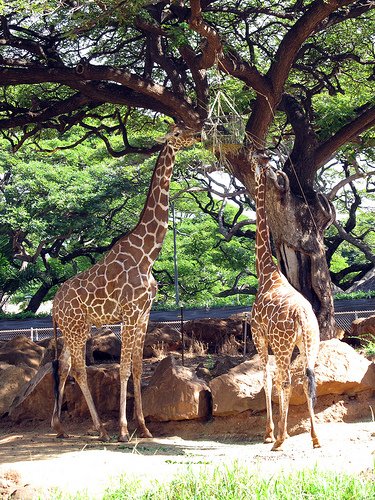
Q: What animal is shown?
A: Giraffe.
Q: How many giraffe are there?
A: Two.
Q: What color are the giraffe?
A: Brown and white.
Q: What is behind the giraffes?
A: Rocks.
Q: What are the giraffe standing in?
A: Dirt.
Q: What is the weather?
A: Sunny.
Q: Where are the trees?
A: Background.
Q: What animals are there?
A: Giraffe.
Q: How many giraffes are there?
A: 2.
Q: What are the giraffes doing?
A: Feeding.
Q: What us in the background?
A: Trees.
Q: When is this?
A: Afternoon.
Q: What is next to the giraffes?
A: Rocks.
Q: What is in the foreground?
A: Grass.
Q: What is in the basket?
A: Food.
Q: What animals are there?
A: Giraffes.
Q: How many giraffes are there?
A: 2.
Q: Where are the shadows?
A: Everywhere.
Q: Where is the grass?
A: Forefront.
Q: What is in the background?
A: Trees.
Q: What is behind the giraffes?
A: Rocks.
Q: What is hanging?
A: Basket.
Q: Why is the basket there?
A: Food.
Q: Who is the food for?
A: Giraffes.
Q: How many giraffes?
A: 2.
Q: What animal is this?
A: Giraffe.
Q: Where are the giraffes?
A: Enclosure in zoo.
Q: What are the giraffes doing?
A: Eating.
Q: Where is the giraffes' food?
A: Hanging from the tree.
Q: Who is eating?
A: Giraffes.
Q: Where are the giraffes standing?
A: Under a tree.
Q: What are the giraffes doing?
A: Eating.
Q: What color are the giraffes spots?
A: Brown.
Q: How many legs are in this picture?
A: Eight.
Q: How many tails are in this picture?
A: Two.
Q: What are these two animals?
A: Giraffes.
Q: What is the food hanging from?
A: A tree.